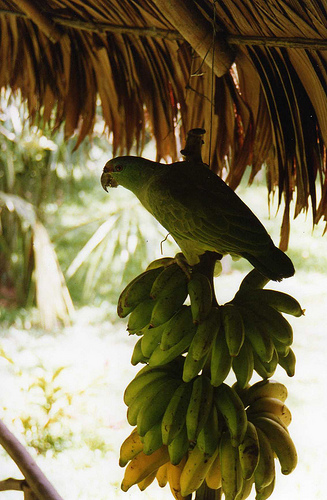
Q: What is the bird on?
A: Bananas.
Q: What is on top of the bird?
A: Feathers.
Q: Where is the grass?
A: On the ground.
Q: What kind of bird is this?
A: Macaw.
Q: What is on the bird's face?
A: A red spot.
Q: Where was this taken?
A: Outdoors in the sun.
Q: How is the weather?
A: Sunny.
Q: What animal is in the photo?
A: Bird.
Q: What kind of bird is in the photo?
A: Parrot.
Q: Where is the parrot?
A: On the bananas.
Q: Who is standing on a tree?
A: A bird.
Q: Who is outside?
A: A bird.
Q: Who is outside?
A: A bird.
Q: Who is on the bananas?
A: A bird.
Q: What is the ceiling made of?
A: Leaves.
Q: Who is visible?
A: A bird.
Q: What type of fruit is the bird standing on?
A: Bananas.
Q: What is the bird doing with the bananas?
A: The bird is standing on top of the bananas.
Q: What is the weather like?
A: It's a bright sunny day.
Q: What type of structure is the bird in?
A: A hut with soft roof.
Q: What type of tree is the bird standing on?
A: A banana tree.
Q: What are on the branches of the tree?
A: Bunches of bananas.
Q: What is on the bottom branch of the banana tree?
A: Yellow bananas.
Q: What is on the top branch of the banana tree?
A: Green bananas.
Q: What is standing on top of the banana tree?
A: A green tropical bird.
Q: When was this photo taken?
A: Daytime.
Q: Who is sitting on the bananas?
A: A bird.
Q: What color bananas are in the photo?
A: Green.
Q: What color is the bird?
A: Green.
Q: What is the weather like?
A: Sunny.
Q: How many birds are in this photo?
A: One.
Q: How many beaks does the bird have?
A: One.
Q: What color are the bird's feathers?
A: Green.